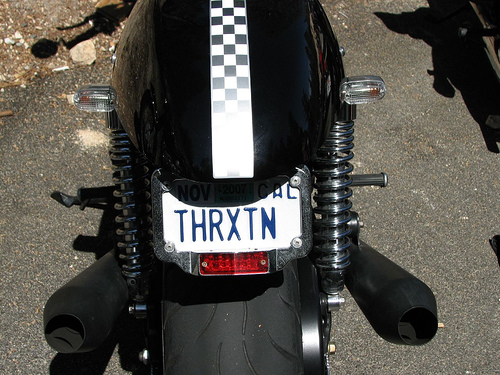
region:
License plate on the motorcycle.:
[163, 194, 309, 243]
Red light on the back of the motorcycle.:
[203, 253, 267, 277]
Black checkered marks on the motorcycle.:
[198, 0, 251, 50]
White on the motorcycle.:
[206, 132, 262, 165]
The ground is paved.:
[411, 131, 474, 190]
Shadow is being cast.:
[394, 16, 455, 47]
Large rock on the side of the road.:
[52, 29, 108, 71]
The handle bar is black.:
[41, 8, 128, 54]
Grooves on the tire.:
[188, 305, 267, 339]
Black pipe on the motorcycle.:
[337, 260, 428, 301]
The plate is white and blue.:
[168, 187, 295, 260]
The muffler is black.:
[42, 257, 118, 353]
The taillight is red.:
[190, 240, 278, 285]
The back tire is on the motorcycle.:
[145, 277, 313, 368]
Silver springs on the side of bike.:
[312, 131, 342, 277]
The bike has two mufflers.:
[41, 282, 451, 355]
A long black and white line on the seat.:
[200, 8, 260, 173]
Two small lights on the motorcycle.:
[58, 70, 131, 125]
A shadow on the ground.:
[392, 11, 482, 163]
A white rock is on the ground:
[18, 38, 131, 71]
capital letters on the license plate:
[175, 207, 280, 242]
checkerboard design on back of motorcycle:
[207, 3, 254, 178]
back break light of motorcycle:
[195, 248, 270, 277]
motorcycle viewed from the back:
[43, 1, 431, 374]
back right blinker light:
[343, 77, 381, 103]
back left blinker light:
[72, 86, 116, 115]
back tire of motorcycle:
[160, 261, 303, 373]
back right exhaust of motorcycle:
[309, 216, 441, 346]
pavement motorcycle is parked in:
[0, 1, 499, 372]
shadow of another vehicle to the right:
[369, 6, 499, 152]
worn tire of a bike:
[147, 275, 310, 371]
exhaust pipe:
[21, 225, 126, 355]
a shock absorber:
[305, 115, 365, 280]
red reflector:
[195, 250, 276, 280]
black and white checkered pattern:
[185, 0, 270, 110]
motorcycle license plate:
[150, 157, 320, 292]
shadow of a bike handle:
[20, 0, 135, 57]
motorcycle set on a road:
[37, 2, 398, 359]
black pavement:
[401, 110, 461, 260]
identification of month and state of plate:
[152, 166, 309, 206]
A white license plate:
[160, 181, 300, 249]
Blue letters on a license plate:
[170, 180, 294, 239]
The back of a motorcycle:
[21, 0, 443, 374]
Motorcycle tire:
[161, 268, 303, 373]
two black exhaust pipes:
[29, 234, 441, 373]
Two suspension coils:
[105, 112, 360, 299]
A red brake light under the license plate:
[195, 250, 270, 273]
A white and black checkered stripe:
[206, 2, 256, 182]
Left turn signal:
[67, 82, 114, 119]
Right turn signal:
[340, 72, 388, 109]